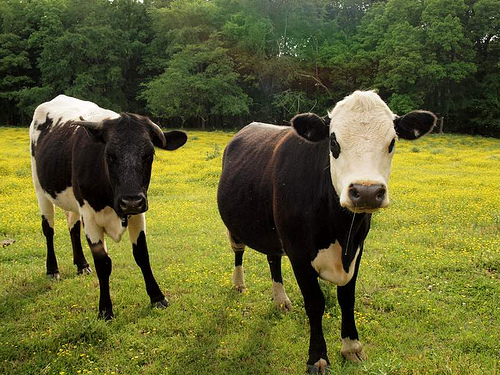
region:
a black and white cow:
[212, 87, 445, 372]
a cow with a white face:
[325, 90, 400, 214]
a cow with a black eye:
[323, 131, 344, 164]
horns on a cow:
[70, 106, 168, 146]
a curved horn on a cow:
[147, 107, 171, 147]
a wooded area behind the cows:
[167, 17, 294, 123]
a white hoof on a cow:
[262, 296, 296, 313]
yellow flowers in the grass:
[447, 136, 492, 261]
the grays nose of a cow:
[340, 175, 391, 220]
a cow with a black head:
[97, 113, 159, 216]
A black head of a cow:
[103, 104, 157, 214]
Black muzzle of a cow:
[119, 191, 147, 217]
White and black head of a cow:
[297, 81, 434, 216]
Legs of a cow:
[298, 322, 371, 372]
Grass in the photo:
[415, 261, 476, 351]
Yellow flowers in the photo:
[420, 223, 484, 259]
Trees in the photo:
[205, 28, 367, 95]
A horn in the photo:
[63, 115, 103, 137]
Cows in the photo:
[13, 79, 446, 373]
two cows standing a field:
[25, 82, 435, 369]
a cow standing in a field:
[25, 90, 186, 331]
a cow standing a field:
[212, 85, 444, 373]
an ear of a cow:
[286, 105, 331, 144]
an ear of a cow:
[394, 107, 439, 144]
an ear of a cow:
[160, 120, 189, 157]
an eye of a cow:
[386, 134, 399, 156]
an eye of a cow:
[324, 130, 342, 160]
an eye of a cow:
[99, 147, 119, 166]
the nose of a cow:
[345, 179, 392, 212]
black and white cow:
[218, 91, 428, 368]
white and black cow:
[27, 93, 186, 319]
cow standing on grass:
[24, 95, 188, 321]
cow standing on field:
[208, 89, 434, 368]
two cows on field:
[28, 88, 437, 373]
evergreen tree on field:
[149, 3, 246, 133]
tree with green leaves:
[268, 3, 362, 58]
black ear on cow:
[293, 111, 328, 143]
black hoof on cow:
[151, 297, 167, 308]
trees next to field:
[2, 1, 498, 134]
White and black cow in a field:
[200, 41, 464, 373]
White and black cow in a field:
[8, 69, 185, 348]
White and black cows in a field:
[9, 47, 433, 372]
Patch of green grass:
[444, 327, 473, 362]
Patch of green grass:
[385, 333, 417, 373]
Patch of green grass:
[250, 329, 294, 374]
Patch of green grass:
[167, 334, 221, 372]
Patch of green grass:
[102, 331, 153, 365]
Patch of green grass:
[16, 331, 69, 363]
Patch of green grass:
[171, 194, 218, 268]